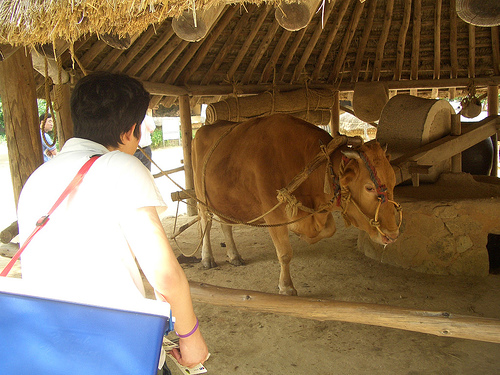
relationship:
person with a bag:
[16, 55, 242, 352] [2, 274, 187, 372]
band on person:
[177, 319, 202, 347] [28, 61, 184, 361]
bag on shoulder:
[1, 145, 171, 374] [83, 147, 167, 217]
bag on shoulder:
[1, 145, 171, 374] [79, 141, 161, 212]